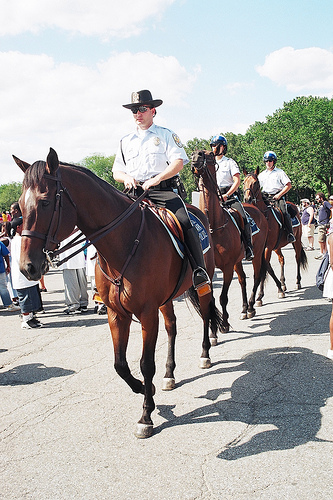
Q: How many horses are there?
A: Three.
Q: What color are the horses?
A: Brown.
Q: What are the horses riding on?
A: Road.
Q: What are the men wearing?
A: Headgear.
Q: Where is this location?
A: Parking lot.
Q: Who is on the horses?
A: Police.